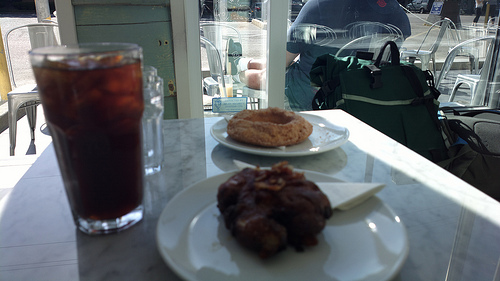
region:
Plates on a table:
[154, 92, 405, 279]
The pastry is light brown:
[223, 103, 312, 152]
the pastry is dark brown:
[217, 160, 327, 254]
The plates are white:
[157, 103, 410, 278]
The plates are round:
[160, 103, 410, 279]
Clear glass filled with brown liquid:
[27, 41, 155, 236]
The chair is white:
[1, 20, 71, 155]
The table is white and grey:
[1, 114, 496, 276]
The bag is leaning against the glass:
[313, 40, 445, 162]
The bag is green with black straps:
[317, 39, 454, 155]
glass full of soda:
[28, 42, 145, 237]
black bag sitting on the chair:
[313, 45, 457, 156]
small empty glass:
[141, 76, 163, 168]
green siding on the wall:
[76, 0, 176, 118]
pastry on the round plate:
[157, 166, 405, 278]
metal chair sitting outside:
[6, 21, 57, 155]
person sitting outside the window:
[285, 3, 412, 100]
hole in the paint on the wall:
[165, 82, 176, 97]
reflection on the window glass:
[289, 22, 476, 66]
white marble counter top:
[8, 112, 492, 276]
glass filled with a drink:
[28, 48, 150, 236]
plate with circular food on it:
[211, 104, 345, 151]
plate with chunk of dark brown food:
[158, 164, 405, 271]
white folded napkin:
[316, 180, 387, 199]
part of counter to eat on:
[408, 173, 496, 276]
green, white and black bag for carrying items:
[323, 54, 466, 147]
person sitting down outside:
[288, 1, 411, 56]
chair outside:
[449, 68, 481, 102]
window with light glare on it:
[290, 2, 495, 45]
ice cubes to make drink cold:
[33, 55, 145, 121]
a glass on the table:
[29, 48, 152, 227]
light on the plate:
[188, 234, 223, 274]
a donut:
[231, 106, 315, 140]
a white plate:
[291, 140, 308, 155]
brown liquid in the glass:
[38, 58, 149, 220]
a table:
[364, 144, 401, 182]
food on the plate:
[219, 163, 330, 248]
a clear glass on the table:
[143, 78, 179, 170]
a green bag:
[349, 70, 434, 118]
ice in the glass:
[56, 69, 128, 119]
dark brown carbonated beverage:
[24, 28, 148, 234]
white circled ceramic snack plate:
[155, 150, 410, 278]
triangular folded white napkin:
[232, 156, 386, 213]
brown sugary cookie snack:
[212, 160, 341, 264]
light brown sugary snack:
[224, 95, 317, 152]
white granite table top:
[0, 104, 499, 277]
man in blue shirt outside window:
[287, 1, 417, 111]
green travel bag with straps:
[311, 30, 463, 159]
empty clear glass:
[132, 71, 167, 176]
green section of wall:
[67, 4, 177, 111]